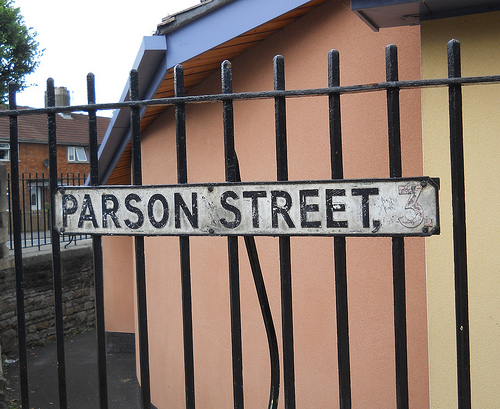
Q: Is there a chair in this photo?
A: No, there are no chairs.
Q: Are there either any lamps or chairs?
A: No, there are no chairs or lamps.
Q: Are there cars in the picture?
A: No, there are no cars.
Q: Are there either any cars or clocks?
A: No, there are no cars or clocks.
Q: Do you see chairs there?
A: No, there are no chairs.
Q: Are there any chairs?
A: No, there are no chairs.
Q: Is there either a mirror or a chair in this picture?
A: No, there are no chairs or mirrors.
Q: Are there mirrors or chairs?
A: No, there are no chairs or mirrors.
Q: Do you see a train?
A: No, there are no trains.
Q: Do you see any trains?
A: No, there are no trains.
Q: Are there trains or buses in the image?
A: No, there are no trains or buses.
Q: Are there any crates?
A: No, there are no crates.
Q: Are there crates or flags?
A: No, there are no crates or flags.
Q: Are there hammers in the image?
A: No, there are no hammers.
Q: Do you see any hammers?
A: No, there are no hammers.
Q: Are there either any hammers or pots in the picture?
A: No, there are no hammers or pots.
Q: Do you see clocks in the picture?
A: No, there are no clocks.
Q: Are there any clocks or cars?
A: No, there are no clocks or cars.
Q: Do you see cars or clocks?
A: No, there are no clocks or cars.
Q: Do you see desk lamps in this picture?
A: No, there are no desk lamps.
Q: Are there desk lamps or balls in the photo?
A: No, there are no desk lamps or balls.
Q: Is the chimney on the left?
A: Yes, the chimney is on the left of the image.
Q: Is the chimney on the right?
A: No, the chimney is on the left of the image.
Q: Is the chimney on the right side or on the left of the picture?
A: The chimney is on the left of the image.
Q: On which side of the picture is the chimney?
A: The chimney is on the left of the image.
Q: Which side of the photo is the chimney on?
A: The chimney is on the left of the image.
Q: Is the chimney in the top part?
A: Yes, the chimney is in the top of the image.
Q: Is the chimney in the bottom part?
A: No, the chimney is in the top of the image.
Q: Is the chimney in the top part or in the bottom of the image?
A: The chimney is in the top of the image.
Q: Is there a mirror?
A: No, there are no mirrors.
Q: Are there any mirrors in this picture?
A: No, there are no mirrors.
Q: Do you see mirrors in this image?
A: No, there are no mirrors.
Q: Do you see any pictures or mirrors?
A: No, there are no mirrors or pictures.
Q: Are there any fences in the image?
A: Yes, there is a fence.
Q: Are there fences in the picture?
A: Yes, there is a fence.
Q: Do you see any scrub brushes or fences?
A: Yes, there is a fence.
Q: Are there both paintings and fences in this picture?
A: No, there is a fence but no paintings.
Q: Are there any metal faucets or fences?
A: Yes, there is a metal fence.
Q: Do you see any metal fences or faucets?
A: Yes, there is a metal fence.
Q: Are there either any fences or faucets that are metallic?
A: Yes, the fence is metallic.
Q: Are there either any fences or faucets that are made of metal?
A: Yes, the fence is made of metal.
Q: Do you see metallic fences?
A: Yes, there is a metal fence.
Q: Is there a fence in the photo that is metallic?
A: Yes, there is a fence that is metallic.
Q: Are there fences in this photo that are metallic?
A: Yes, there is a fence that is metallic.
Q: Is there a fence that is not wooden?
A: Yes, there is a metallic fence.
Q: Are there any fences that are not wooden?
A: Yes, there is a metallic fence.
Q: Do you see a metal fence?
A: Yes, there is a fence that is made of metal.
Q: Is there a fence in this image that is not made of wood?
A: Yes, there is a fence that is made of metal.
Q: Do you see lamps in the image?
A: No, there are no lamps.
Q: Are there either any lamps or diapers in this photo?
A: No, there are no lamps or diapers.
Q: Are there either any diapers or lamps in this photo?
A: No, there are no lamps or diapers.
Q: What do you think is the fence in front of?
A: The fence is in front of the building.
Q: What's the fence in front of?
A: The fence is in front of the building.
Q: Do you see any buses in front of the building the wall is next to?
A: No, there is a fence in front of the building.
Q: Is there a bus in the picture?
A: No, there are no buses.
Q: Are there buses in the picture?
A: No, there are no buses.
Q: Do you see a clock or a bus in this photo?
A: No, there are no buses or clocks.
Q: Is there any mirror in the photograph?
A: No, there are no mirrors.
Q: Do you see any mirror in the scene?
A: No, there are no mirrors.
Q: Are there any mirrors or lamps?
A: No, there are no mirrors or lamps.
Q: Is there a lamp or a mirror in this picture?
A: No, there are no mirrors or lamps.